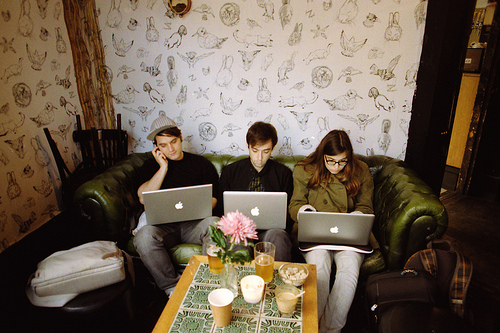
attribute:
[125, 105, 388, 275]
people — on couch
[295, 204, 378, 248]
laptop — apple, in photo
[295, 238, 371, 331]
pants — white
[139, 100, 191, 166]
head — man's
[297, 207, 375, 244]
laptop — grey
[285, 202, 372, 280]
lap — her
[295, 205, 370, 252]
laptop — apple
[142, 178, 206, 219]
macbook — gray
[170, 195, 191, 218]
logo — apple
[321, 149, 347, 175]
face — woman's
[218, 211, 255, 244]
flower — pink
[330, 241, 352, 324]
leg — woman's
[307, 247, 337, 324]
leg — woman's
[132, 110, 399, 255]
people — three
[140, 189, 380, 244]
laptops — three, silver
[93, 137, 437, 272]
sofa — green colored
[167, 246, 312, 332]
table — green center, yellow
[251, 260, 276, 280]
liquid — yellow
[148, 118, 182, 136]
cap — baseball, grey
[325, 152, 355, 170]
glasses — pair, brown rimmed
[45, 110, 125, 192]
chair — brown , dark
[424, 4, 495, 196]
doorway — dark, brown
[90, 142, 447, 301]
couch — dark green leather 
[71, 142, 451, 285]
couch — GREEN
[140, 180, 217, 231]
laptop — OPEN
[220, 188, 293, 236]
laptop — OPEN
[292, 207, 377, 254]
laptop — OPEN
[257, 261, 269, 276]
liquid — YELLOW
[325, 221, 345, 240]
apple — WHITE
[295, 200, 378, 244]
computer — SILVER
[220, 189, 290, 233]
computer — SILVER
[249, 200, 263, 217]
apple — WHITE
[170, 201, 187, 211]
apple — WHITE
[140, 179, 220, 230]
computer — SILVER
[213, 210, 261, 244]
flower — PINK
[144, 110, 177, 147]
cap — BASEBALL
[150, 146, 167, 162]
phone — CELL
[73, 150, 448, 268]
sofa — GREEN, LEATHER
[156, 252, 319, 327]
table — COFFEE, WOODEN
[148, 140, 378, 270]
people — sitting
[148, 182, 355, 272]
laptops — open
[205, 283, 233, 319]
cup — plastic, sitting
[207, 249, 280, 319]
vase — sitting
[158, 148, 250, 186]
shirt — black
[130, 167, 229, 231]
laptop — apple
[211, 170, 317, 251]
laptop — silver, white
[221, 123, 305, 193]
man — asian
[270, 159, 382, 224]
jacket — green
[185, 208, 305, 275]
rose — huge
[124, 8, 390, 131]
wall — designed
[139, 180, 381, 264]
macbook — apple logo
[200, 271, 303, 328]
cup — coffee 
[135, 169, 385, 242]
computer — open MacBook laptop 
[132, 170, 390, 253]
computer — open MacBook laptop 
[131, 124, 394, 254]
logo — Apple corporate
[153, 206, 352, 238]
logo — Apple corporate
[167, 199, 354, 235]
logo — Apple corporate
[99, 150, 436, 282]
couch — dark green leather 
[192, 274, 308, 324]
cup — brown paper 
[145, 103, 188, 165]
cap —  light grey 